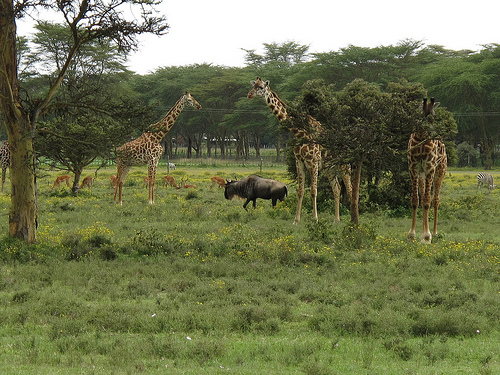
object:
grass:
[3, 161, 498, 374]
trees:
[0, 3, 498, 161]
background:
[1, 0, 496, 172]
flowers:
[1, 219, 497, 270]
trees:
[1, 0, 499, 249]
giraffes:
[109, 76, 451, 243]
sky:
[13, 0, 500, 80]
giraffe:
[406, 95, 446, 246]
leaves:
[291, 75, 460, 174]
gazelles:
[53, 172, 229, 193]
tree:
[1, 0, 171, 241]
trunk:
[0, 0, 40, 247]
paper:
[185, 334, 193, 342]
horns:
[183, 74, 434, 109]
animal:
[222, 173, 289, 214]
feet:
[407, 227, 439, 246]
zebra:
[473, 172, 497, 189]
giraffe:
[247, 77, 357, 225]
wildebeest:
[222, 176, 290, 211]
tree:
[277, 79, 460, 225]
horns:
[252, 75, 262, 85]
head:
[245, 77, 273, 102]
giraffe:
[111, 92, 202, 206]